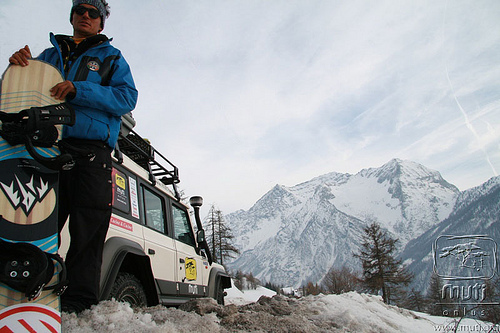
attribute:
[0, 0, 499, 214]
sky — cloudy 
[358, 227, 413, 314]
tree — green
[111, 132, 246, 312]
car — white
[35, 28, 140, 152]
jacket — blue, black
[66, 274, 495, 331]
snow — dirt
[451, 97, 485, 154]
streaks — white 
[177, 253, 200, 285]
picture — yellow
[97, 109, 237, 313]
jeep — WITH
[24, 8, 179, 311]
man — IN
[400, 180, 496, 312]
mountain — ARE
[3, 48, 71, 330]
snowboard — blue , tan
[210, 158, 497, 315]
mountains — COVERED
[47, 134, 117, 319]
pants — black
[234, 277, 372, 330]
snow — black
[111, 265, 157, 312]
wheel well — plastic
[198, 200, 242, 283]
trees — thinly-leafed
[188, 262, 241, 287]
bumper — black 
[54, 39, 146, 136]
jacket — black , blue 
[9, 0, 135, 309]
man — WEARING, HOLDING, IN, STANDING, yong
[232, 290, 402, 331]
snow — dirty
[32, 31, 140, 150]
coat — blue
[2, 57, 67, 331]
snowboard — graphic, white, blue, colorful